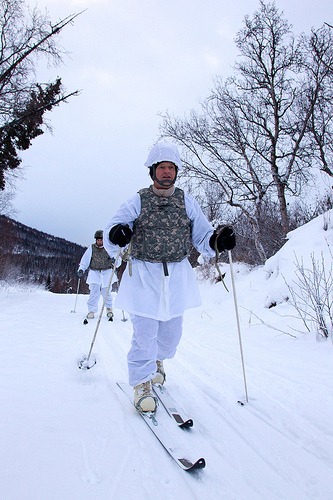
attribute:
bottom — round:
[77, 351, 100, 372]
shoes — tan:
[115, 368, 180, 414]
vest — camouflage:
[127, 182, 194, 262]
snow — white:
[15, 360, 70, 418]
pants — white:
[99, 319, 191, 422]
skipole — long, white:
[225, 252, 258, 408]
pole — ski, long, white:
[225, 249, 253, 407]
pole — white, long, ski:
[78, 244, 123, 370]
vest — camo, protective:
[124, 186, 193, 279]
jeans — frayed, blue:
[127, 264, 195, 407]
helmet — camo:
[93, 228, 103, 238]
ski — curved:
[116, 379, 205, 472]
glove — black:
[109, 222, 132, 246]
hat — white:
[142, 141, 184, 171]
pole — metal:
[220, 255, 276, 420]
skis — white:
[99, 352, 234, 480]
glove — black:
[208, 224, 237, 250]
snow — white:
[33, 305, 60, 344]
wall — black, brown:
[183, 87, 212, 113]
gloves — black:
[106, 219, 239, 258]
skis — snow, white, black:
[115, 370, 211, 472]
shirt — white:
[137, 188, 205, 310]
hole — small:
[267, 299, 277, 309]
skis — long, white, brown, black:
[115, 376, 205, 471]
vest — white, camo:
[88, 244, 112, 268]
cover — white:
[144, 141, 184, 170]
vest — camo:
[132, 185, 191, 263]